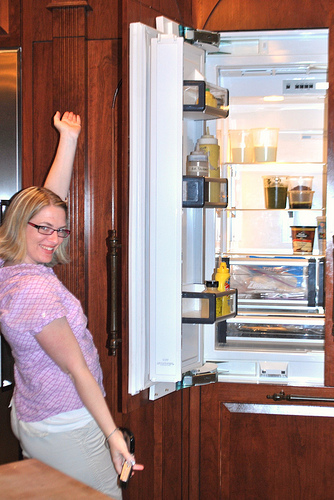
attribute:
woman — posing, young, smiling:
[0, 106, 150, 499]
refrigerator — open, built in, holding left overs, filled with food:
[105, 14, 331, 500]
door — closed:
[178, 384, 332, 500]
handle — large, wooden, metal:
[102, 227, 121, 364]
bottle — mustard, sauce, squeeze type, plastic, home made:
[201, 278, 222, 319]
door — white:
[107, 13, 228, 412]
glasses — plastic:
[28, 221, 74, 240]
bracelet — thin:
[103, 425, 124, 453]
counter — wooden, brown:
[0, 455, 125, 500]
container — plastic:
[251, 127, 280, 163]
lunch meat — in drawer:
[230, 262, 305, 302]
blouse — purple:
[1, 257, 109, 423]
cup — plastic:
[261, 176, 292, 209]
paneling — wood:
[1, 3, 125, 415]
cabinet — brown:
[15, 0, 191, 499]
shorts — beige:
[10, 403, 128, 498]